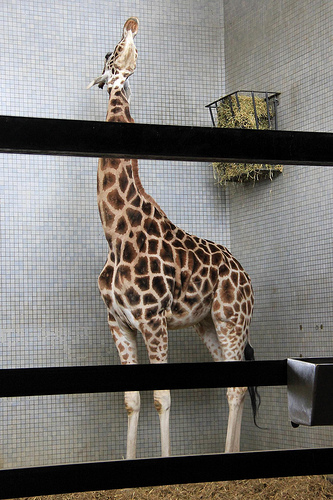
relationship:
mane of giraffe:
[133, 157, 170, 224] [87, 17, 269, 459]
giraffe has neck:
[87, 17, 269, 459] [95, 81, 139, 152]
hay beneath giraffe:
[35, 449, 299, 498] [44, 13, 291, 481]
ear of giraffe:
[80, 66, 113, 89] [69, 15, 261, 485]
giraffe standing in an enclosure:
[69, 15, 261, 485] [1, 112, 321, 498]